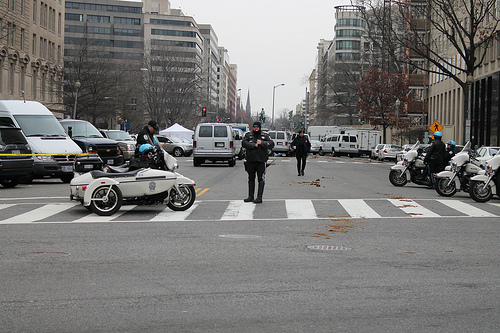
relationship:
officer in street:
[237, 121, 276, 206] [1, 142, 497, 328]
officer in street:
[133, 118, 164, 209] [1, 142, 497, 328]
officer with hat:
[133, 118, 164, 209] [147, 119, 159, 131]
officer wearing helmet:
[422, 128, 453, 189] [434, 130, 443, 139]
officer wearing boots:
[237, 121, 276, 206] [242, 179, 254, 202]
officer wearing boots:
[237, 121, 276, 206] [252, 178, 267, 207]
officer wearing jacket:
[237, 121, 276, 206] [240, 130, 274, 164]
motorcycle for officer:
[68, 130, 197, 216] [133, 118, 164, 209]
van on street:
[190, 122, 239, 168] [1, 142, 497, 328]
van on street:
[1, 94, 86, 185] [1, 142, 497, 328]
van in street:
[1, 94, 86, 185] [1, 142, 497, 328]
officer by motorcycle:
[133, 118, 164, 209] [68, 130, 197, 216]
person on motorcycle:
[443, 140, 461, 173] [387, 138, 457, 186]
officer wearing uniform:
[237, 121, 276, 206] [240, 133, 277, 199]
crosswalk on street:
[1, 199, 497, 226] [1, 142, 497, 328]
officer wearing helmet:
[133, 118, 164, 209] [434, 130, 443, 139]